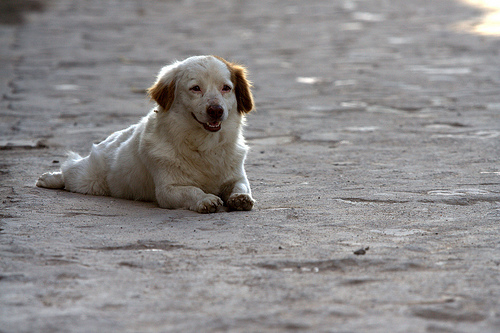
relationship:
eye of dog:
[185, 82, 212, 96] [35, 55, 255, 215]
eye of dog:
[221, 77, 231, 97] [35, 55, 255, 215]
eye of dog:
[221, 84, 232, 92] [35, 55, 255, 215]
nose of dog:
[203, 101, 229, 116] [35, 55, 255, 215]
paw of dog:
[228, 190, 258, 210] [35, 55, 255, 215]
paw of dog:
[191, 185, 223, 212] [35, 55, 255, 215]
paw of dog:
[196, 195, 224, 213] [35, 55, 255, 215]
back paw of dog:
[32, 167, 75, 195] [35, 55, 255, 215]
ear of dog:
[145, 65, 181, 114] [35, 55, 255, 215]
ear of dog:
[213, 57, 253, 114] [35, 55, 255, 215]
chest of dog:
[185, 149, 223, 187] [35, 55, 255, 215]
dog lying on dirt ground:
[34, 49, 271, 229] [0, 0, 500, 333]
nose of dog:
[203, 101, 229, 116] [34, 49, 271, 229]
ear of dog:
[224, 59, 255, 115] [35, 55, 255, 215]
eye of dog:
[185, 82, 212, 96] [34, 49, 271, 229]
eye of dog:
[221, 84, 232, 92] [34, 49, 271, 229]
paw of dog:
[228, 190, 258, 210] [34, 49, 271, 229]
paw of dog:
[196, 195, 224, 213] [34, 49, 271, 229]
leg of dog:
[28, 168, 76, 195] [35, 55, 255, 215]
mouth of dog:
[185, 111, 229, 134] [35, 55, 255, 215]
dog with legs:
[34, 49, 271, 229] [26, 161, 259, 215]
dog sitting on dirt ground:
[34, 49, 271, 229] [0, 0, 500, 333]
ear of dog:
[145, 65, 181, 114] [34, 49, 271, 229]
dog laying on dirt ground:
[34, 49, 271, 229] [0, 0, 500, 333]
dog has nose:
[35, 55, 255, 215] [203, 101, 229, 116]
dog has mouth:
[34, 49, 271, 229] [185, 105, 228, 132]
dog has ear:
[34, 49, 271, 229] [146, 61, 178, 118]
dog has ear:
[34, 49, 271, 229] [226, 58, 258, 118]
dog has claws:
[34, 49, 271, 229] [184, 190, 263, 219]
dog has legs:
[34, 49, 271, 229] [31, 145, 255, 216]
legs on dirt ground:
[31, 145, 255, 216] [0, 0, 500, 333]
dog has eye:
[34, 49, 271, 229] [184, 79, 204, 99]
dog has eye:
[34, 49, 271, 229] [216, 77, 237, 99]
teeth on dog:
[198, 118, 229, 129] [35, 55, 255, 215]